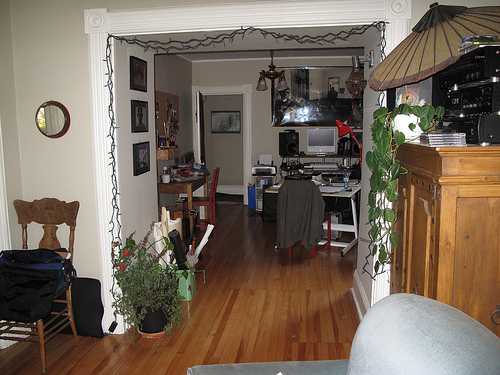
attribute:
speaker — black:
[278, 131, 300, 156]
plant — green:
[110, 220, 195, 348]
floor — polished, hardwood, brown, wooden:
[0, 194, 357, 373]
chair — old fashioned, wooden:
[2, 197, 79, 374]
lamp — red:
[335, 121, 362, 163]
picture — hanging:
[208, 110, 242, 134]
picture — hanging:
[128, 53, 149, 92]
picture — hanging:
[130, 100, 149, 132]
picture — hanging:
[132, 143, 151, 176]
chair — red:
[276, 178, 331, 259]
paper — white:
[257, 154, 272, 167]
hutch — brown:
[388, 139, 499, 339]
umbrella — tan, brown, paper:
[369, 2, 499, 92]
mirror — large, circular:
[36, 100, 71, 139]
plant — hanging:
[362, 104, 443, 279]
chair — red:
[181, 168, 220, 233]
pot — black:
[132, 301, 170, 333]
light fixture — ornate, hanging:
[256, 51, 288, 92]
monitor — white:
[305, 129, 338, 158]